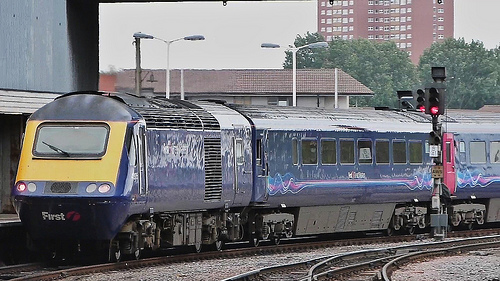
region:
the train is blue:
[239, 102, 491, 230]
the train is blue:
[247, 89, 396, 195]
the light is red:
[391, 76, 453, 114]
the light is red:
[403, 86, 450, 123]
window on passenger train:
[24, 107, 120, 166]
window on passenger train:
[286, 127, 306, 168]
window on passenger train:
[300, 128, 320, 167]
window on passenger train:
[318, 131, 340, 167]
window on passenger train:
[334, 132, 357, 169]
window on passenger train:
[353, 126, 378, 168]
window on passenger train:
[367, 126, 397, 171]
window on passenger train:
[387, 130, 416, 172]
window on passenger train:
[406, 133, 431, 173]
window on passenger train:
[458, 133, 491, 170]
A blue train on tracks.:
[11, 87, 499, 265]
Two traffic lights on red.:
[411, 83, 445, 115]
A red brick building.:
[317, 1, 455, 65]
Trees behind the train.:
[281, 28, 499, 109]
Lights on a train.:
[16, 180, 111, 193]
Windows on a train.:
[289, 133, 498, 166]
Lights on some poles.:
[131, 28, 330, 107]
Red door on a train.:
[441, 130, 457, 195]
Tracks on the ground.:
[21, 226, 498, 278]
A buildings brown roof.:
[113, 68, 375, 96]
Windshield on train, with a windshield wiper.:
[28, 116, 110, 161]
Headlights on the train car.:
[10, 176, 137, 204]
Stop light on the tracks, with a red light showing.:
[417, 63, 455, 245]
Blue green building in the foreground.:
[0, 0, 105, 246]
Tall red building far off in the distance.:
[315, 0, 455, 65]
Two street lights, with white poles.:
[126, 25, 347, 104]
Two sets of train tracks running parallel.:
[5, 221, 498, 279]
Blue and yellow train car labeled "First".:
[8, 80, 253, 256]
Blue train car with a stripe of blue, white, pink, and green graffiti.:
[235, 95, 435, 246]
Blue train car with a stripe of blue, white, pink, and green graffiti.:
[418, 103, 498, 233]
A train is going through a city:
[1, 35, 494, 260]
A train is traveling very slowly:
[16, 33, 486, 264]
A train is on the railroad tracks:
[26, 48, 471, 268]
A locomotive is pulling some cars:
[5, 61, 491, 276]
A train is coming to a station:
[10, 30, 483, 275]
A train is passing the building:
[8, 40, 493, 260]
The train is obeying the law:
[17, 37, 482, 269]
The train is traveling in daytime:
[11, 36, 487, 276]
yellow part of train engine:
[6, 111, 134, 191]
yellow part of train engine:
[11, 103, 139, 184]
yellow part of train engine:
[3, 105, 133, 192]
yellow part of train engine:
[6, 107, 145, 193]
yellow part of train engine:
[11, 108, 134, 193]